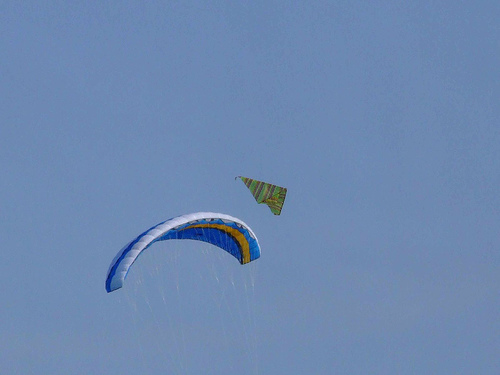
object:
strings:
[114, 224, 270, 374]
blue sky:
[0, 0, 499, 374]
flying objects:
[231, 175, 286, 217]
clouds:
[417, 112, 477, 281]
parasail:
[98, 210, 265, 293]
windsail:
[103, 210, 263, 373]